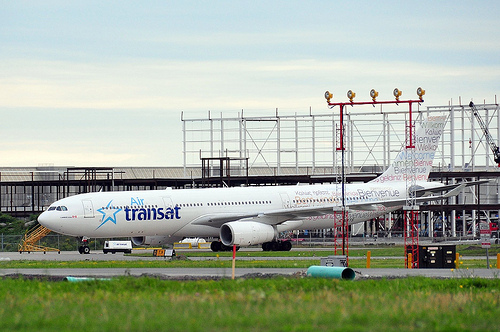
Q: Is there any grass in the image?
A: Yes, there is grass.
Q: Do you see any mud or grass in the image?
A: Yes, there is grass.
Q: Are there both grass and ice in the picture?
A: No, there is grass but no ice.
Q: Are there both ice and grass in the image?
A: No, there is grass but no ice.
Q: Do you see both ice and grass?
A: No, there is grass but no ice.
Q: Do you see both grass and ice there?
A: No, there is grass but no ice.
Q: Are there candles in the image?
A: No, there are no candles.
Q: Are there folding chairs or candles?
A: No, there are no candles or folding chairs.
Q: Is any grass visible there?
A: Yes, there is grass.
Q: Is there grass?
A: Yes, there is grass.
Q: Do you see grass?
A: Yes, there is grass.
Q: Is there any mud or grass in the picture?
A: Yes, there is grass.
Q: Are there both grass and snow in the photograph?
A: No, there is grass but no snow.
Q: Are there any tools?
A: No, there are no tools.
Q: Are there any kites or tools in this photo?
A: No, there are no tools or kites.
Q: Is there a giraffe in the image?
A: No, there are no giraffes.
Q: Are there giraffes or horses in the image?
A: No, there are no giraffes or horses.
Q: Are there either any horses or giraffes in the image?
A: No, there are no giraffes or horses.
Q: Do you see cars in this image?
A: No, there are no cars.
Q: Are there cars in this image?
A: No, there are no cars.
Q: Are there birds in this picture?
A: No, there are no birds.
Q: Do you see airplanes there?
A: Yes, there is an airplane.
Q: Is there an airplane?
A: Yes, there is an airplane.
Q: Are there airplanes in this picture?
A: Yes, there is an airplane.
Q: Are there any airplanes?
A: Yes, there is an airplane.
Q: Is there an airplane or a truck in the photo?
A: Yes, there is an airplane.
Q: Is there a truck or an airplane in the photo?
A: Yes, there is an airplane.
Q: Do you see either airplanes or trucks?
A: Yes, there is an airplane.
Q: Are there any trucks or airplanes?
A: Yes, there is an airplane.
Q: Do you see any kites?
A: No, there are no kites.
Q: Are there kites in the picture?
A: No, there are no kites.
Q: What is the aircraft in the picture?
A: The aircraft is an airplane.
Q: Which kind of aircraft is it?
A: The aircraft is an airplane.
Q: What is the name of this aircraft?
A: This is an airplane.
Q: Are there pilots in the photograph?
A: No, there are no pilots.